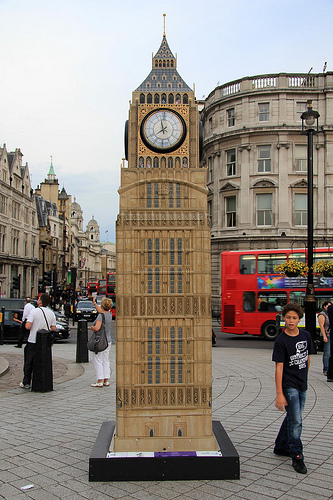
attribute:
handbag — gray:
[83, 310, 109, 350]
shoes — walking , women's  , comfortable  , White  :
[90, 378, 109, 387]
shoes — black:
[289, 451, 307, 474]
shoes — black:
[271, 443, 291, 457]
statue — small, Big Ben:
[90, 33, 265, 358]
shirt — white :
[268, 329, 316, 390]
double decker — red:
[217, 213, 328, 345]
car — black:
[68, 294, 104, 323]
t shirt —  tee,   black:
[271, 330, 317, 392]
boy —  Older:
[271, 301, 311, 474]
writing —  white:
[288, 352, 307, 371]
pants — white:
[93, 337, 110, 380]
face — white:
[139, 106, 187, 154]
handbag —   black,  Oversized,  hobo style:
[85, 313, 107, 354]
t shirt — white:
[24, 306, 57, 344]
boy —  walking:
[272, 304, 324, 416]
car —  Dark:
[74, 298, 98, 319]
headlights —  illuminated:
[76, 308, 97, 313]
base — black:
[87, 418, 240, 480]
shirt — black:
[270, 329, 321, 402]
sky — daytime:
[0, 5, 332, 241]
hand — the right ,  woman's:
[92, 295, 96, 302]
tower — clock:
[115, 18, 232, 459]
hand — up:
[89, 292, 101, 309]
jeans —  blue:
[272, 388, 304, 455]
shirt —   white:
[26, 306, 55, 342]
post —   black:
[302, 133, 315, 352]